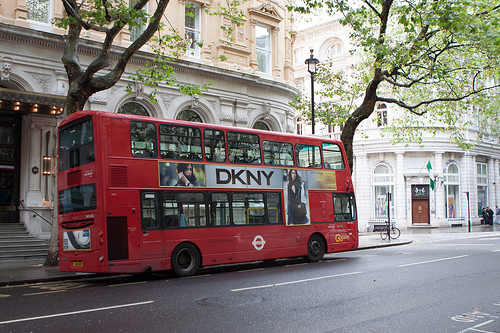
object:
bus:
[68, 102, 376, 271]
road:
[223, 259, 466, 307]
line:
[234, 267, 354, 288]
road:
[262, 260, 488, 309]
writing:
[450, 304, 499, 331]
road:
[321, 244, 496, 282]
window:
[234, 12, 278, 70]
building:
[144, 15, 360, 75]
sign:
[188, 150, 332, 207]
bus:
[52, 105, 356, 253]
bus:
[58, 110, 352, 247]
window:
[180, 3, 205, 54]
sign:
[155, 157, 340, 227]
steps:
[12, 216, 75, 284]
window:
[142, 186, 283, 226]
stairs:
[0, 223, 50, 277]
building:
[6, 3, 299, 300]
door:
[4, 129, 25, 211]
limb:
[79, 3, 145, 73]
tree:
[58, 1, 173, 107]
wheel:
[305, 237, 325, 263]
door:
[414, 184, 433, 226]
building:
[294, 10, 482, 232]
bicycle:
[380, 221, 399, 238]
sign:
[385, 187, 393, 243]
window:
[141, 190, 300, 230]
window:
[333, 190, 356, 221]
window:
[378, 100, 389, 128]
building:
[294, 30, 484, 229]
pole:
[384, 192, 394, 239]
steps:
[4, 225, 53, 273]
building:
[4, 3, 302, 251]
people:
[482, 203, 483, 207]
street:
[364, 219, 479, 248]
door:
[406, 185, 429, 225]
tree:
[307, 14, 478, 167]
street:
[42, 227, 484, 319]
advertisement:
[150, 161, 339, 226]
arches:
[114, 92, 278, 131]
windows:
[125, 141, 282, 161]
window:
[131, 127, 156, 156]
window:
[224, 134, 262, 164]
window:
[260, 142, 294, 165]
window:
[332, 194, 356, 224]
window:
[57, 182, 95, 213]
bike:
[378, 220, 399, 240]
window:
[444, 159, 464, 222]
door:
[2, 111, 23, 226]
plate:
[69, 257, 86, 270]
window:
[250, 17, 279, 75]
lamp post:
[301, 45, 338, 133]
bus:
[51, 108, 356, 276]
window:
[297, 145, 324, 166]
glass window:
[141, 195, 159, 229]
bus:
[58, 113, 358, 266]